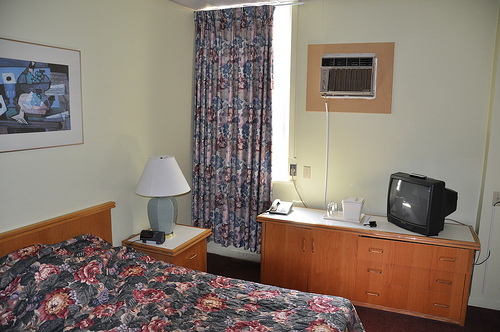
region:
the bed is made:
[95, 267, 195, 291]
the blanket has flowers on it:
[65, 257, 119, 306]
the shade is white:
[151, 166, 175, 186]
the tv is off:
[398, 192, 418, 215]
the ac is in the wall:
[313, 49, 385, 104]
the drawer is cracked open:
[357, 232, 402, 247]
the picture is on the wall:
[64, 97, 95, 133]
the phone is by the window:
[267, 188, 295, 225]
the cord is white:
[322, 136, 330, 161]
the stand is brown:
[170, 244, 212, 271]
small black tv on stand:
[386, 172, 458, 236]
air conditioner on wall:
[321, 53, 385, 99]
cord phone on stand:
[268, 194, 291, 215]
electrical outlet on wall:
[287, 161, 297, 180]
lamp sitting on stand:
[135, 157, 190, 234]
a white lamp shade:
[139, 152, 185, 199]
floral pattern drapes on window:
[195, 7, 269, 246]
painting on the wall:
[2, 39, 87, 158]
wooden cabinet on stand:
[264, 224, 310, 287]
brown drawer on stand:
[355, 235, 427, 272]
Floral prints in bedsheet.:
[26, 240, 248, 330]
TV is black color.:
[373, 160, 453, 246]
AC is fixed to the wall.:
[301, 45, 408, 111]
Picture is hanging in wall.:
[0, 20, 126, 166]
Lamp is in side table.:
[126, 156, 212, 261]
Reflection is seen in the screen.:
[375, 171, 435, 236]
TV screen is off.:
[375, 162, 450, 232]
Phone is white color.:
[256, 188, 307, 228]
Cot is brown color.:
[6, 202, 90, 302]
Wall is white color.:
[119, 34, 184, 120]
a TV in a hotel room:
[381, 160, 465, 242]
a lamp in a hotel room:
[136, 154, 189, 229]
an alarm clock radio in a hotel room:
[138, 228, 167, 245]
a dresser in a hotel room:
[260, 218, 490, 321]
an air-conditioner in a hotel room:
[315, 48, 381, 107]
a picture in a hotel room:
[4, 34, 89, 156]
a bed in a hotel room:
[6, 239, 360, 327]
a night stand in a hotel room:
[123, 223, 213, 270]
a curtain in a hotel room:
[193, 8, 266, 256]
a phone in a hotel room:
[261, 191, 301, 217]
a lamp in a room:
[134, 145, 221, 257]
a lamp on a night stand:
[129, 135, 259, 271]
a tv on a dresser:
[359, 162, 490, 256]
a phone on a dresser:
[262, 182, 311, 222]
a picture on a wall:
[10, 28, 153, 158]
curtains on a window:
[174, 8, 375, 220]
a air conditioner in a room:
[293, 25, 426, 147]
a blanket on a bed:
[39, 192, 421, 323]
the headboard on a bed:
[1, 165, 176, 265]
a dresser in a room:
[247, 183, 490, 297]